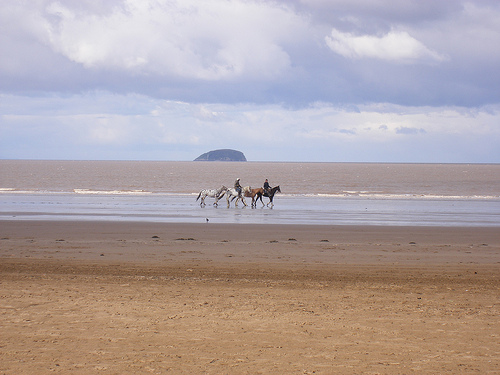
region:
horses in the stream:
[193, 167, 292, 213]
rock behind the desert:
[194, 144, 251, 166]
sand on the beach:
[11, 209, 498, 371]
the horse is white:
[194, 184, 227, 209]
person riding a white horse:
[228, 173, 247, 211]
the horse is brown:
[254, 186, 284, 208]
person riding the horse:
[262, 177, 271, 195]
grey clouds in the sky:
[0, 7, 498, 170]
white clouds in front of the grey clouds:
[312, 19, 445, 66]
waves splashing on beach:
[42, 187, 492, 206]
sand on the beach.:
[110, 311, 468, 359]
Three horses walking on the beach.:
[185, 180, 282, 208]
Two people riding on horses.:
[230, 170, 271, 192]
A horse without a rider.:
[190, 180, 227, 210]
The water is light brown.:
[45, 161, 195, 181]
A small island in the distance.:
[190, 136, 250, 161]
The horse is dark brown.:
[255, 181, 285, 214]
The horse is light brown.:
[238, 182, 264, 208]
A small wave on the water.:
[67, 176, 157, 196]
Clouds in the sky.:
[0, 0, 487, 129]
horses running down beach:
[46, 152, 486, 339]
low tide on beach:
[0, 155, 499, 373]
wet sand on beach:
[1, 185, 496, 332]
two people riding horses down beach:
[9, 76, 497, 227]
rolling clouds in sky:
[8, 3, 497, 180]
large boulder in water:
[157, 115, 309, 177]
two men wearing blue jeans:
[152, 145, 308, 215]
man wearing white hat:
[192, 170, 247, 203]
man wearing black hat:
[249, 162, 294, 207]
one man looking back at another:
[176, 163, 286, 215]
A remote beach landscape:
[2, 1, 497, 368]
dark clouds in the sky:
[3, 7, 496, 157]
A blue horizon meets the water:
[5, 107, 495, 167]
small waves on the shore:
[282, 186, 498, 203]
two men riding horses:
[196, 178, 286, 212]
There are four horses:
[197, 185, 284, 212]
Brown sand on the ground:
[1, 221, 496, 369]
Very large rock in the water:
[189, 140, 257, 163]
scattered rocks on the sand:
[146, 233, 205, 244]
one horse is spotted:
[193, 183, 228, 205]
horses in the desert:
[188, 170, 301, 240]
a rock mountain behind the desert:
[194, 143, 249, 173]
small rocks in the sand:
[100, 224, 428, 267]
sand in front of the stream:
[0, 202, 497, 372]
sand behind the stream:
[1, 154, 496, 196]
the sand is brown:
[2, 213, 484, 369]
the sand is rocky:
[4, 219, 491, 373]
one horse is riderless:
[197, 182, 224, 214]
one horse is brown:
[250, 184, 287, 208]